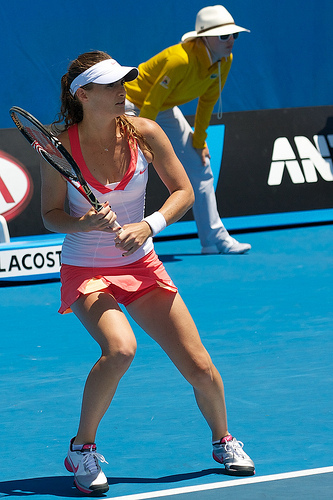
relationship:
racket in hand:
[8, 104, 125, 237] [83, 196, 116, 233]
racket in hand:
[8, 104, 125, 237] [109, 214, 147, 255]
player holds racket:
[24, 47, 258, 493] [8, 104, 125, 237]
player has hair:
[24, 47, 258, 493] [66, 50, 106, 73]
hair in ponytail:
[66, 50, 106, 73] [55, 72, 79, 127]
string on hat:
[215, 59, 224, 120] [176, 7, 246, 39]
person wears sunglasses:
[120, 3, 262, 253] [216, 32, 242, 41]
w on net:
[32, 127, 58, 156] [16, 111, 74, 171]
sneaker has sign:
[64, 440, 109, 493] [66, 455, 81, 471]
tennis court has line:
[204, 252, 331, 471] [256, 461, 332, 483]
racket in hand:
[11, 102, 96, 210] [84, 192, 121, 233]